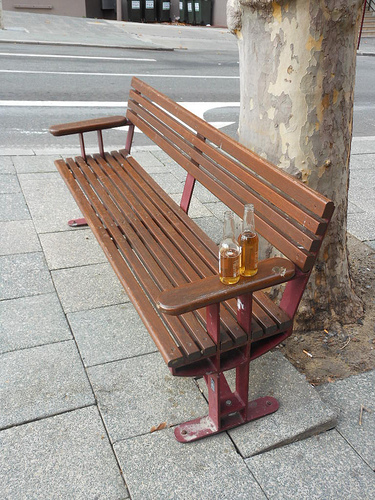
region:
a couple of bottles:
[218, 204, 259, 286]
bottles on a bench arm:
[217, 202, 259, 292]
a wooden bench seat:
[47, 70, 326, 440]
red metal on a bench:
[174, 327, 299, 452]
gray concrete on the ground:
[3, 302, 121, 468]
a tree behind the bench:
[237, 67, 362, 342]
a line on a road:
[6, 95, 135, 111]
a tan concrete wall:
[5, 0, 96, 18]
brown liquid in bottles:
[216, 203, 264, 282]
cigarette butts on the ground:
[293, 319, 344, 366]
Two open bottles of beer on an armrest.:
[217, 204, 258, 283]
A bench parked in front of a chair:
[51, 75, 336, 444]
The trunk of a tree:
[227, 2, 365, 326]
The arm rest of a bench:
[47, 115, 127, 152]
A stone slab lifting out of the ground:
[193, 346, 335, 458]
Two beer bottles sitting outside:
[219, 203, 259, 284]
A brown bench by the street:
[47, 77, 335, 444]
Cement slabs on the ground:
[2, 291, 145, 494]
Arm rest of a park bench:
[157, 255, 296, 317]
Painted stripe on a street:
[12, 96, 107, 109]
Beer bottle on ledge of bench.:
[239, 212, 277, 300]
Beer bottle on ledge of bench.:
[213, 244, 241, 282]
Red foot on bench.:
[191, 379, 272, 426]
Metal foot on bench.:
[193, 380, 285, 439]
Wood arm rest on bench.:
[164, 280, 209, 294]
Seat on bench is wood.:
[107, 186, 185, 286]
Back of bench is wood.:
[157, 107, 240, 175]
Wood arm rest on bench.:
[54, 109, 119, 128]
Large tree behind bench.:
[246, 23, 347, 160]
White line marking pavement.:
[33, 59, 124, 87]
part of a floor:
[125, 436, 152, 475]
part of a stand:
[216, 397, 243, 439]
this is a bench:
[76, 95, 196, 276]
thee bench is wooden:
[77, 109, 200, 238]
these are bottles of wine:
[210, 201, 261, 277]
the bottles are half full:
[215, 199, 263, 282]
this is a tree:
[238, 16, 359, 120]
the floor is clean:
[6, 269, 100, 383]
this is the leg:
[205, 369, 255, 427]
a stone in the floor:
[1, 342, 95, 428]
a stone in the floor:
[4, 400, 128, 496]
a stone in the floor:
[88, 349, 211, 440]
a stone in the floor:
[109, 411, 264, 497]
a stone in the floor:
[193, 351, 335, 452]